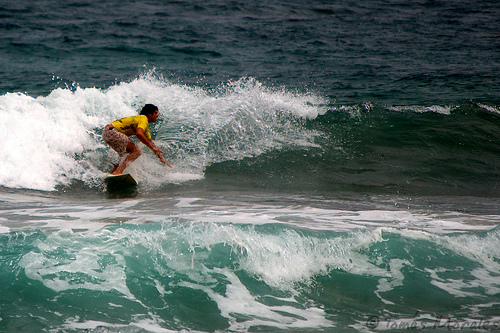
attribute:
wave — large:
[2, 64, 497, 202]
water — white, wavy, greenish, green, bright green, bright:
[4, 5, 492, 333]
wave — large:
[0, 217, 499, 332]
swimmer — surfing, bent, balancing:
[99, 101, 173, 177]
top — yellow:
[109, 114, 153, 140]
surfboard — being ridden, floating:
[104, 164, 141, 195]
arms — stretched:
[132, 126, 170, 170]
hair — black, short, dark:
[141, 105, 158, 115]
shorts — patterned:
[101, 125, 132, 156]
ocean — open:
[0, 0, 498, 103]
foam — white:
[2, 74, 314, 184]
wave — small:
[387, 60, 493, 91]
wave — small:
[302, 37, 330, 50]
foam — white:
[384, 90, 456, 116]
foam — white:
[473, 99, 499, 116]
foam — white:
[195, 222, 383, 289]